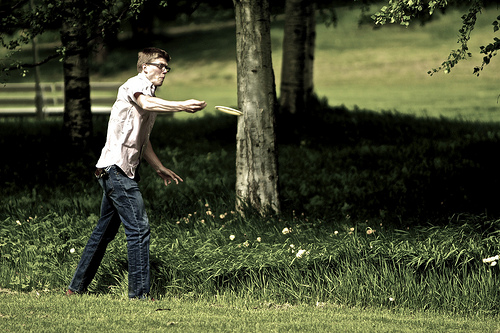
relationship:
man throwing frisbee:
[82, 34, 187, 312] [206, 98, 250, 129]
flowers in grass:
[207, 208, 323, 262] [389, 264, 440, 303]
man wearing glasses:
[82, 34, 187, 312] [140, 59, 181, 80]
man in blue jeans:
[82, 34, 187, 312] [77, 161, 164, 288]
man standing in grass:
[82, 34, 187, 312] [389, 264, 440, 303]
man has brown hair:
[82, 34, 187, 312] [129, 50, 186, 54]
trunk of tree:
[230, 4, 290, 93] [57, 63, 95, 193]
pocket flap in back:
[85, 160, 110, 193] [82, 156, 92, 184]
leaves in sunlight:
[384, 10, 458, 33] [367, 23, 383, 39]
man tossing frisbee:
[82, 34, 187, 312] [206, 98, 250, 129]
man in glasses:
[82, 34, 187, 312] [140, 59, 181, 80]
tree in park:
[57, 63, 95, 193] [336, 31, 421, 106]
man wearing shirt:
[82, 34, 187, 312] [114, 66, 167, 192]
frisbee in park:
[206, 98, 250, 129] [336, 31, 421, 106]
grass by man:
[389, 264, 440, 303] [82, 34, 187, 312]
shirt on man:
[114, 66, 167, 192] [82, 34, 187, 312]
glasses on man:
[140, 59, 181, 80] [82, 34, 187, 312]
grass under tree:
[389, 264, 440, 303] [57, 63, 95, 193]